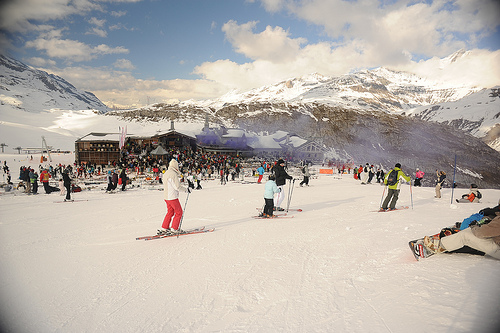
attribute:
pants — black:
[261, 196, 275, 216]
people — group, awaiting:
[3, 164, 134, 203]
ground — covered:
[0, 152, 498, 331]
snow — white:
[0, 160, 499, 329]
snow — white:
[267, 223, 402, 290]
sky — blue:
[0, 2, 497, 113]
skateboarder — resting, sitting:
[402, 208, 499, 268]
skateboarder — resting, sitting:
[378, 155, 405, 225]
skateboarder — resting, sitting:
[448, 182, 492, 211]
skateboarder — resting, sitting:
[149, 159, 196, 245]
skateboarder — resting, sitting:
[256, 170, 285, 230]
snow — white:
[0, 48, 498, 330]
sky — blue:
[122, 11, 228, 56]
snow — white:
[0, 205, 494, 331]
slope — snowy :
[1, 169, 498, 331]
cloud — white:
[206, 19, 217, 32]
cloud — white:
[177, 57, 182, 67]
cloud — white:
[111, 57, 141, 72]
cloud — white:
[81, 24, 110, 40]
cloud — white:
[220, 19, 308, 66]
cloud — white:
[259, 0, 285, 13]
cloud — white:
[287, 2, 390, 46]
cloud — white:
[380, 4, 444, 57]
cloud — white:
[434, 32, 465, 59]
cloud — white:
[44, 27, 61, 37]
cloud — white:
[85, 15, 105, 26]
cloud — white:
[87, 28, 107, 38]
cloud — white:
[21, 37, 94, 62]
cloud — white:
[30, 54, 47, 66]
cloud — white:
[438, 9, 485, 37]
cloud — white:
[467, 31, 481, 45]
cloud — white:
[386, 4, 439, 58]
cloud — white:
[430, 0, 448, 10]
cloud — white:
[440, 32, 455, 42]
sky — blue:
[8, 5, 481, 130]